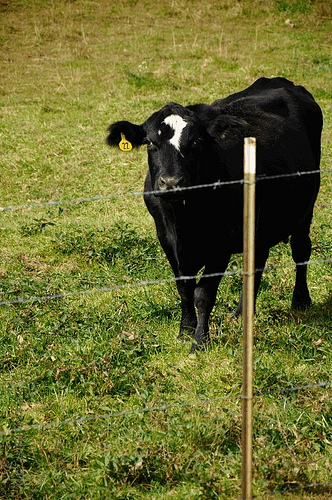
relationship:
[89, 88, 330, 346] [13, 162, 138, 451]
cow near fence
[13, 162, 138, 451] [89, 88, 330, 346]
fence near cow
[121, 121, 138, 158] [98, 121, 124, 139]
tag in ear